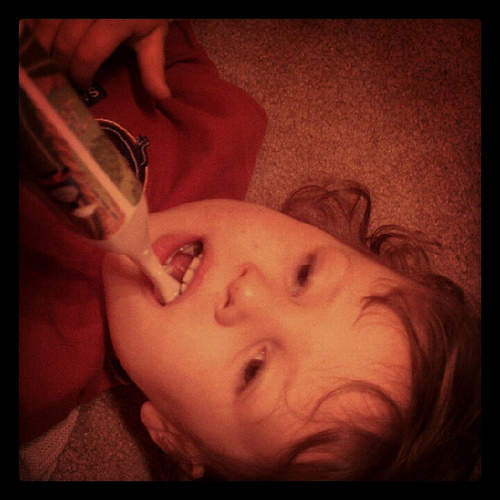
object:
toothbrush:
[8, 53, 183, 305]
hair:
[388, 288, 485, 455]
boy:
[0, 0, 499, 493]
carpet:
[251, 32, 493, 199]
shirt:
[18, 21, 268, 452]